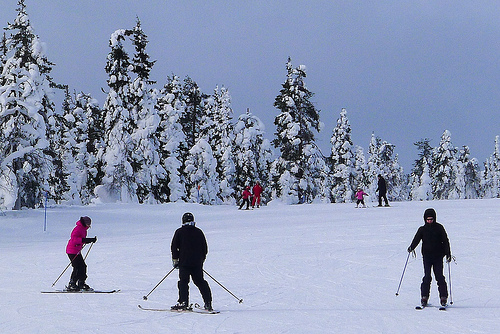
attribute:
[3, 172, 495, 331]
snow — white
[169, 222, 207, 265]
jacket — black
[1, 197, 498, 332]
plain — flat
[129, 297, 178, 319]
ski — long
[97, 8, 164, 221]
tree — covered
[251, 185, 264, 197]
jacket — red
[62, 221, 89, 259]
snow jacket — pink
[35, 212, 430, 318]
snow — white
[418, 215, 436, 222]
sunglasses — dark, black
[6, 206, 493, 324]
snow — white, field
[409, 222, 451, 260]
jacket — black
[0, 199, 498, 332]
snow — white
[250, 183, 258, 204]
outfit — bright red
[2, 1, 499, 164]
sky — blue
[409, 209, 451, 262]
jacket — black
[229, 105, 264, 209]
tree — tall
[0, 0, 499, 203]
trees — large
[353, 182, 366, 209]
child — small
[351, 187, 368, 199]
jacket — bright pink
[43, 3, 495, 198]
sky — blue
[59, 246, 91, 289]
pants — black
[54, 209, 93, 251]
jacket — puffy, bright, pink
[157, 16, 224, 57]
clouds — white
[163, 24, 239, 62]
clouds — white